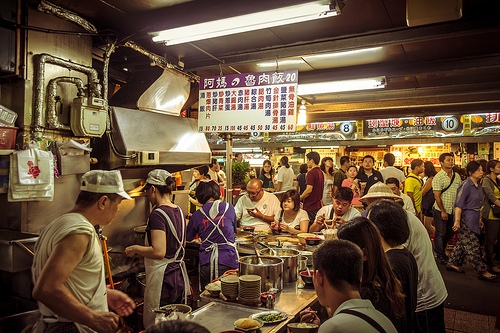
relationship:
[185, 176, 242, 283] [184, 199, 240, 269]
woman wears purple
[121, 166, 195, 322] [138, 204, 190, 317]
woman wears apron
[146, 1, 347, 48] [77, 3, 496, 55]
light suspended from ceiling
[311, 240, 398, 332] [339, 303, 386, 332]
people has strap on shoulder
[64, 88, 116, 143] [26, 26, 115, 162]
gas meter mounted on wall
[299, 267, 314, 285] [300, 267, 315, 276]
bowl with soup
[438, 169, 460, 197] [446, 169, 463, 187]
strap on shoulder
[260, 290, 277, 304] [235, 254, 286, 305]
cup next to pot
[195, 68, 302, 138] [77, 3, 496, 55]
sign hanging from ceiling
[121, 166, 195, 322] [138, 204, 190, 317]
worker worn apron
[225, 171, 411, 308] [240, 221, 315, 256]
people eating food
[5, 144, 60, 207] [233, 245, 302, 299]
bags to take food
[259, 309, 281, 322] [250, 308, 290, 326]
food on a plate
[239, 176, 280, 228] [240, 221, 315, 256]
man eating food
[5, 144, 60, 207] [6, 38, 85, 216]
bags hanging from oven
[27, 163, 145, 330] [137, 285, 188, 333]
man making food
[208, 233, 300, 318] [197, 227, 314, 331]
food on top counter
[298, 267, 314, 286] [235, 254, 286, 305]
soup on pot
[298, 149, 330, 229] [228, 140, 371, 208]
man walking down market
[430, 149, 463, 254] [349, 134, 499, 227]
man walking down market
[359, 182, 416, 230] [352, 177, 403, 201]
man wearing hat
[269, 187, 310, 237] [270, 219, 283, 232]
woman eating food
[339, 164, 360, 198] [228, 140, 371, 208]
woman walking down market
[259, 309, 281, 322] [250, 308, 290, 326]
food on plate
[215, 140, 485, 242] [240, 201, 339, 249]
people eating food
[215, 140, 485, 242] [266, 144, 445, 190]
people waiting in line